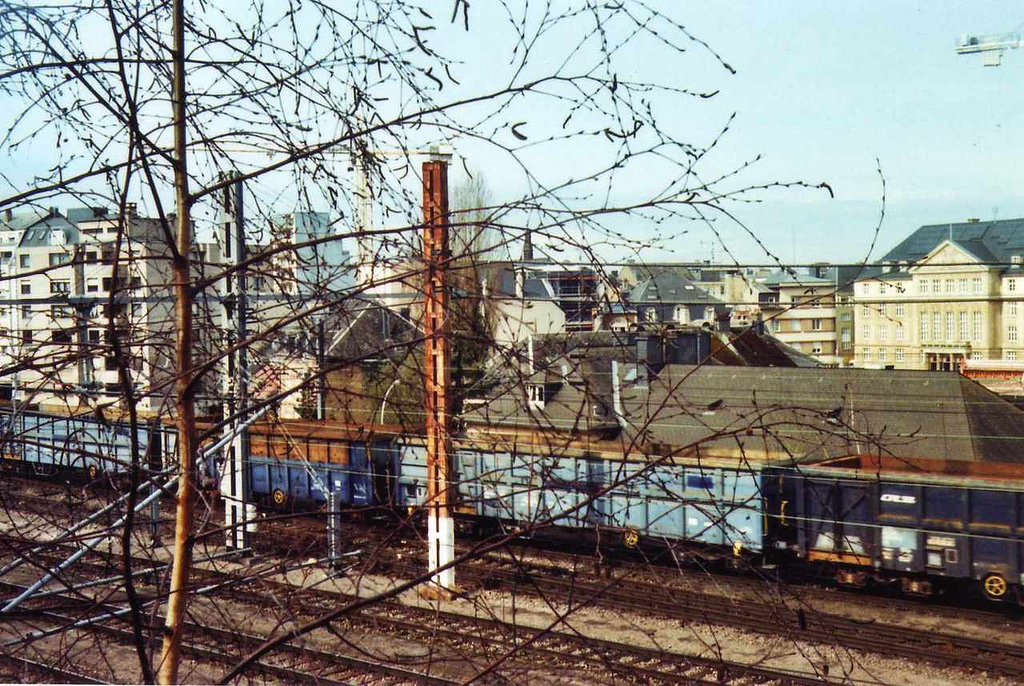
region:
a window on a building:
[915, 273, 929, 290]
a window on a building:
[926, 265, 942, 297]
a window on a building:
[943, 276, 953, 293]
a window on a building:
[950, 272, 963, 293]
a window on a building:
[915, 304, 926, 330]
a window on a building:
[925, 307, 941, 330]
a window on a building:
[953, 305, 961, 335]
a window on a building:
[962, 304, 978, 344]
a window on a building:
[643, 304, 660, 311]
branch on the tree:
[329, 610, 362, 640]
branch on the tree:
[669, 481, 780, 533]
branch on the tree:
[529, 198, 637, 247]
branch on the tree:
[58, 351, 122, 418]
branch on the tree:
[257, 338, 305, 374]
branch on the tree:
[283, 127, 405, 182]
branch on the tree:
[744, 571, 815, 629]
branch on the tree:
[753, 398, 858, 459]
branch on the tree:
[46, 318, 145, 407]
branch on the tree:
[311, 462, 428, 549]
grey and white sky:
[669, 12, 873, 105]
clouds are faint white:
[740, 97, 836, 263]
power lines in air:
[532, 173, 859, 383]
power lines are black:
[544, 208, 833, 363]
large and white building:
[757, 214, 1005, 377]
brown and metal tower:
[374, 149, 461, 582]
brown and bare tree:
[5, 47, 452, 649]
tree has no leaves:
[0, 6, 716, 398]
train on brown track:
[184, 380, 997, 608]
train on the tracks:
[21, 384, 998, 612]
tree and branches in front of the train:
[13, 161, 821, 683]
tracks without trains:
[6, 480, 1021, 684]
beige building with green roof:
[853, 210, 1008, 375]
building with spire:
[484, 219, 571, 350]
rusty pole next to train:
[416, 162, 477, 593]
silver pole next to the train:
[209, 158, 264, 548]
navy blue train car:
[780, 455, 1022, 595]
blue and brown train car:
[160, 401, 389, 523]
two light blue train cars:
[10, 387, 760, 571]